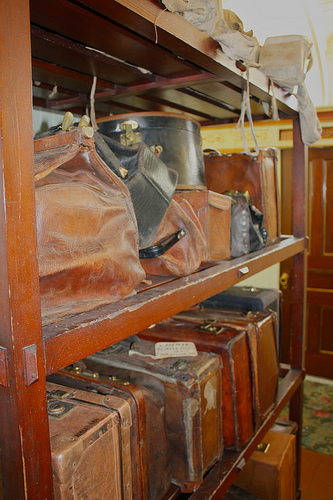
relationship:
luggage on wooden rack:
[29, 100, 283, 306] [0, 0, 311, 497]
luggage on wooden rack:
[50, 279, 292, 492] [0, 0, 311, 497]